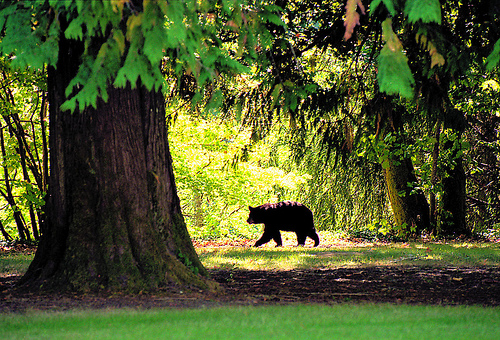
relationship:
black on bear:
[268, 215, 292, 226] [246, 202, 321, 250]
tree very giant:
[28, 1, 225, 307] [138, 112, 158, 257]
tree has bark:
[28, 1, 225, 307] [70, 113, 109, 209]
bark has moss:
[70, 113, 109, 209] [84, 164, 105, 180]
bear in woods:
[246, 202, 321, 250] [325, 21, 483, 262]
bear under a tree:
[246, 202, 321, 250] [28, 1, 225, 307]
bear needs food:
[246, 202, 321, 250] [193, 242, 243, 249]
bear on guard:
[246, 202, 321, 250] [255, 227, 269, 247]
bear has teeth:
[246, 202, 321, 250] [249, 218, 254, 224]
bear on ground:
[246, 202, 321, 250] [198, 246, 450, 268]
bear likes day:
[246, 202, 321, 250] [158, 109, 283, 205]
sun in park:
[156, 102, 281, 153] [9, 243, 500, 337]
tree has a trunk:
[28, 1, 225, 307] [50, 112, 185, 325]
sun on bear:
[156, 102, 281, 153] [246, 202, 321, 250]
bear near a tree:
[246, 202, 321, 250] [28, 1, 225, 307]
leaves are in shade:
[379, 23, 445, 68] [224, 275, 439, 311]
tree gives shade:
[28, 1, 225, 307] [224, 275, 439, 311]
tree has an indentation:
[28, 1, 225, 307] [54, 133, 93, 207]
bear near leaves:
[246, 202, 321, 250] [327, 226, 371, 246]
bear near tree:
[246, 202, 321, 250] [28, 1, 225, 307]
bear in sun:
[246, 202, 321, 250] [156, 102, 281, 153]